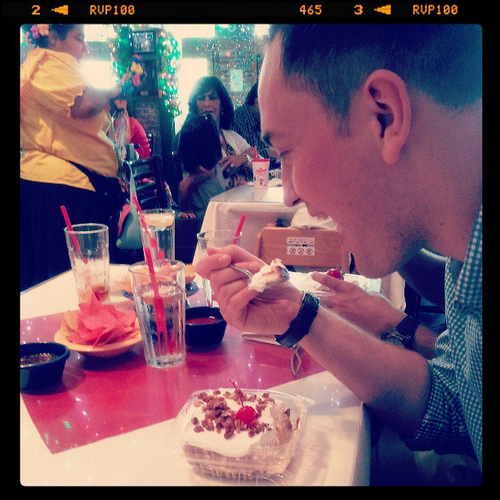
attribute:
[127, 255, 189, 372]
glass — water, clear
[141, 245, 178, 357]
straw — red, long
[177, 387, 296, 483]
dessert — white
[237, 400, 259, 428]
cherry — red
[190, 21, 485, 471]
man — eating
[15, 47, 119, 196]
blouse — yellow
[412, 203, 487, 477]
shirt — blue, green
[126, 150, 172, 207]
chair — high, wooden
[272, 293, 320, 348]
watch — black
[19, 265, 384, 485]
table — white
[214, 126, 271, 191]
t-shirt — white